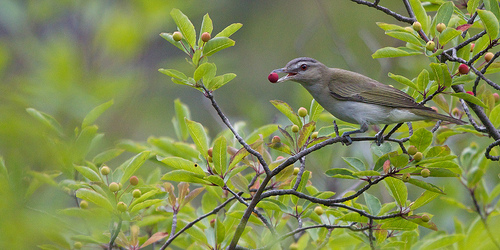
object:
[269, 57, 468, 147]
bird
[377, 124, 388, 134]
leg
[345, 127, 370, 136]
leg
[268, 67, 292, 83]
beak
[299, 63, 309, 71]
eye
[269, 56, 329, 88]
head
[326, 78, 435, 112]
wing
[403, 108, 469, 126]
tail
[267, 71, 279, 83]
berry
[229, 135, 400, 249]
branch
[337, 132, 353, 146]
foot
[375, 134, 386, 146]
foot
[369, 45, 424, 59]
leaf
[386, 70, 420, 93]
leaf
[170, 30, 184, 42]
berry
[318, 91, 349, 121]
breast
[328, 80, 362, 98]
feather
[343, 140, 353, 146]
talon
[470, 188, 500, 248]
branch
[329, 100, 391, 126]
belly